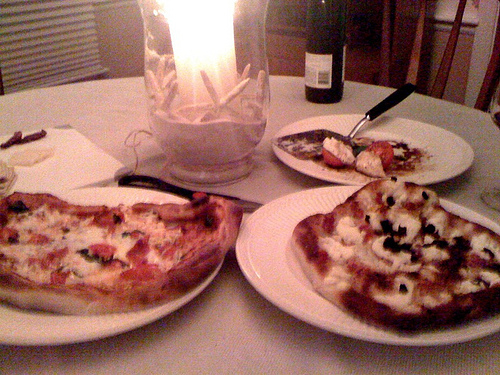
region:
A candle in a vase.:
[120, 0, 280, 170]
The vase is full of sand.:
[140, 92, 262, 157]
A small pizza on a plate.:
[240, 175, 495, 330]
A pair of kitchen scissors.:
[115, 160, 267, 214]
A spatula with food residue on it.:
[270, 80, 420, 170]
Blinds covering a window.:
[0, 0, 115, 100]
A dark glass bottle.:
[275, 0, 370, 105]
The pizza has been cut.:
[0, 175, 246, 330]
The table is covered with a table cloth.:
[0, 63, 495, 365]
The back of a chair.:
[357, 0, 497, 110]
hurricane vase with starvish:
[102, 0, 297, 182]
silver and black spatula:
[271, 99, 424, 194]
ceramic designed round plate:
[247, 186, 315, 318]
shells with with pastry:
[318, 129, 392, 177]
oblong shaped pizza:
[297, 181, 497, 316]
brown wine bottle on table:
[295, 12, 354, 98]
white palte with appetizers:
[26, 123, 98, 186]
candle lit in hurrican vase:
[175, 0, 241, 108]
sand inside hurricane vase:
[152, 113, 264, 176]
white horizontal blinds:
[0, 20, 110, 77]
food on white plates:
[0, 102, 493, 336]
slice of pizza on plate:
[294, 193, 476, 314]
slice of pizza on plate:
[3, 215, 197, 275]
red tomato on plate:
[370, 137, 395, 164]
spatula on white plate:
[262, 100, 396, 153]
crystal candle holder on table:
[123, 0, 255, 160]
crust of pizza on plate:
[186, 234, 231, 258]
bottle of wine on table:
[296, 18, 341, 104]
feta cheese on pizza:
[391, 217, 423, 242]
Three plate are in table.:
[25, 115, 456, 352]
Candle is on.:
[157, 26, 262, 156]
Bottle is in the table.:
[290, 5, 365, 105]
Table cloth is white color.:
[60, 85, 140, 140]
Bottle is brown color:
[305, 20, 360, 100]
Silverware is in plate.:
[285, 105, 410, 185]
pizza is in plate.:
[6, 185, 227, 315]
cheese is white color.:
[21, 217, 112, 279]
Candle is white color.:
[148, 5, 247, 120]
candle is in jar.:
[168, 25, 259, 151]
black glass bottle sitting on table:
[305, 2, 360, 104]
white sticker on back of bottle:
[300, 47, 337, 91]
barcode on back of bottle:
[310, 68, 335, 89]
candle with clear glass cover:
[152, 2, 271, 174]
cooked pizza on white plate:
[0, 190, 228, 312]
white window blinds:
[0, 2, 117, 79]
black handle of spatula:
[345, 81, 425, 130]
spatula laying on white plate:
[277, 77, 435, 173]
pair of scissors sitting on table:
[117, 170, 267, 224]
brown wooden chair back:
[381, 0, 498, 77]